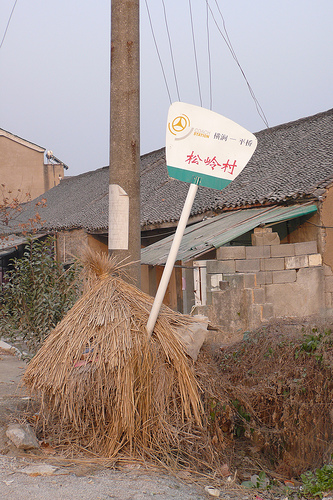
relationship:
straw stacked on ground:
[16, 246, 220, 463] [1, 328, 330, 498]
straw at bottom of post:
[12, 231, 227, 477] [139, 173, 197, 347]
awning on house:
[138, 203, 322, 262] [14, 111, 328, 353]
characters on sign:
[186, 152, 238, 178] [159, 95, 259, 199]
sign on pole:
[168, 87, 258, 199] [140, 176, 201, 340]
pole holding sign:
[150, 176, 200, 345] [163, 89, 261, 190]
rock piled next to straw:
[2, 420, 41, 452] [16, 237, 213, 474]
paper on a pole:
[107, 184, 129, 249] [109, 0, 138, 289]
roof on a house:
[0, 111, 322, 236] [0, 110, 322, 364]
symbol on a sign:
[166, 111, 191, 136] [163, 99, 258, 192]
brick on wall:
[242, 271, 256, 286] [206, 240, 332, 329]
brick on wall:
[245, 243, 270, 262] [193, 238, 331, 347]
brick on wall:
[231, 272, 255, 288] [191, 229, 332, 336]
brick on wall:
[252, 229, 281, 243] [191, 229, 332, 336]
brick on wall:
[246, 243, 270, 257] [191, 229, 332, 336]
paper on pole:
[107, 184, 129, 249] [110, 0, 140, 291]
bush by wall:
[2, 233, 81, 341] [53, 231, 86, 274]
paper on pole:
[107, 184, 129, 249] [106, 0, 142, 285]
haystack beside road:
[25, 250, 202, 457] [1, 353, 71, 495]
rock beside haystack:
[4, 424, 41, 453] [38, 239, 204, 463]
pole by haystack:
[106, 0, 142, 285] [35, 240, 189, 460]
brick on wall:
[245, 243, 270, 262] [198, 221, 322, 331]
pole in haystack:
[144, 183, 196, 338] [46, 243, 187, 459]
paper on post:
[107, 184, 129, 249] [106, 0, 141, 279]